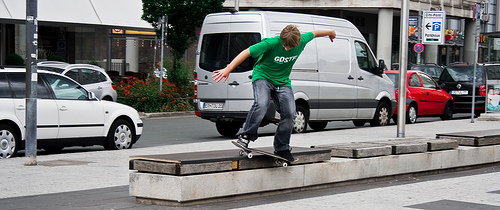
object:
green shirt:
[248, 32, 315, 88]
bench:
[126, 129, 500, 207]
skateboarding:
[206, 15, 379, 178]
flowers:
[126, 76, 136, 83]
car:
[353, 70, 455, 127]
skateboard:
[231, 141, 289, 168]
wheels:
[239, 151, 244, 157]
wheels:
[246, 153, 253, 159]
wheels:
[274, 159, 280, 165]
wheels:
[281, 162, 287, 168]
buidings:
[398, 2, 493, 89]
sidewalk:
[0, 116, 498, 200]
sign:
[421, 11, 447, 45]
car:
[438, 62, 500, 115]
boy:
[210, 24, 335, 161]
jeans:
[238, 79, 296, 153]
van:
[194, 11, 396, 137]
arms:
[223, 38, 277, 72]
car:
[390, 63, 444, 82]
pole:
[23, 0, 37, 166]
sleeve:
[249, 41, 269, 58]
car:
[0, 67, 144, 158]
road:
[147, 110, 198, 136]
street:
[12, 91, 488, 151]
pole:
[396, 1, 409, 139]